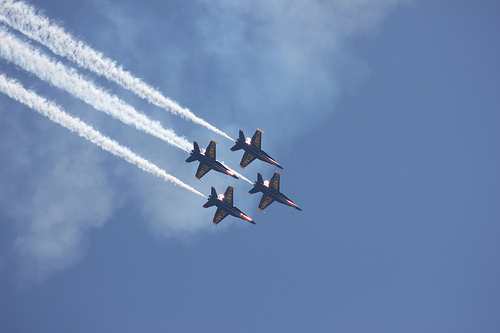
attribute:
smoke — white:
[0, 1, 253, 198]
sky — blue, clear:
[342, 81, 467, 226]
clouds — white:
[30, 25, 142, 153]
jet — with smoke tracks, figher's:
[231, 127, 286, 166]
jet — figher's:
[186, 140, 240, 179]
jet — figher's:
[249, 171, 301, 211]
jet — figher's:
[202, 185, 254, 224]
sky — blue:
[316, 77, 486, 321]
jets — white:
[155, 113, 269, 217]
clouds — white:
[183, 25, 315, 99]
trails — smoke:
[15, 30, 184, 190]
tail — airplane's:
[242, 170, 265, 197]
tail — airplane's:
[224, 121, 244, 152]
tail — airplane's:
[176, 137, 200, 165]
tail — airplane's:
[197, 180, 219, 209]